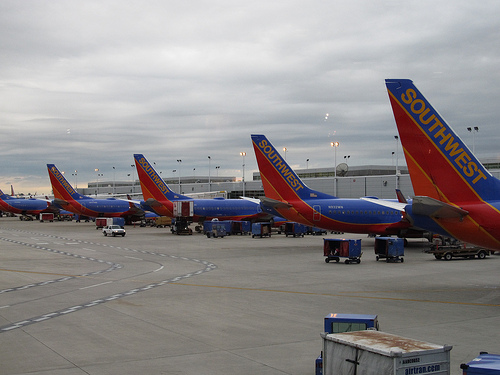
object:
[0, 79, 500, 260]
row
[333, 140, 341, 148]
lights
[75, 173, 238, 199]
building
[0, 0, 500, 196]
sky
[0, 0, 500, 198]
cloudy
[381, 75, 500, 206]
wing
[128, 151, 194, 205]
wing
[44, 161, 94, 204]
wing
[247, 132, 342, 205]
wing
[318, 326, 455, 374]
container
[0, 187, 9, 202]
wing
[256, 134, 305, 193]
word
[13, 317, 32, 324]
line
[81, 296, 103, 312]
line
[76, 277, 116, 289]
line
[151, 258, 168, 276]
line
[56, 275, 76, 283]
line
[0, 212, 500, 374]
ground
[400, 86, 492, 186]
southwest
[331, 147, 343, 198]
light posts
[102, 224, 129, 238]
car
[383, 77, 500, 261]
airplane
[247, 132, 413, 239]
airplane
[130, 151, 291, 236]
airplane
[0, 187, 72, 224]
airplane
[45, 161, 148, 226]
plane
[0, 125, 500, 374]
airport